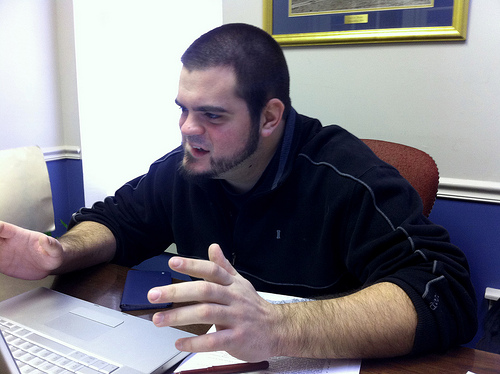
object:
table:
[59, 244, 498, 372]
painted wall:
[3, 2, 497, 349]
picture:
[257, 1, 474, 48]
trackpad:
[43, 310, 201, 340]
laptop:
[6, 259, 180, 367]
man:
[45, 10, 472, 352]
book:
[97, 246, 205, 324]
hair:
[165, 18, 321, 151]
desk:
[77, 255, 301, 331]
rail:
[43, 142, 498, 209]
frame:
[275, 24, 458, 39]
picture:
[263, 2, 467, 51]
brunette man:
[83, 19, 383, 285]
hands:
[8, 197, 278, 360]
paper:
[181, 287, 367, 372]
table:
[1, 225, 497, 369]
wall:
[437, 201, 499, 331]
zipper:
[244, 196, 323, 279]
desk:
[3, 261, 483, 371]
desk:
[14, 169, 499, 371]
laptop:
[0, 285, 212, 367]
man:
[43, 50, 471, 355]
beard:
[175, 121, 276, 191]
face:
[153, 14, 304, 189]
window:
[103, 43, 179, 131]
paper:
[171, 283, 361, 372]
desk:
[0, 249, 500, 372]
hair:
[274, 299, 416, 346]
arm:
[157, 173, 478, 362]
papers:
[292, 347, 359, 369]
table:
[415, 344, 480, 371]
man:
[136, 69, 486, 329]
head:
[175, 22, 290, 183]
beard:
[176, 115, 261, 182]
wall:
[220, 1, 499, 197]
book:
[119, 265, 172, 311]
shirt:
[72, 112, 477, 353]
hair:
[309, 297, 374, 339]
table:
[0, 261, 499, 371]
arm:
[146, 239, 476, 364]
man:
[17, 20, 471, 372]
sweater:
[69, 129, 469, 346]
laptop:
[4, 292, 206, 370]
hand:
[143, 242, 268, 363]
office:
[3, 3, 494, 370]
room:
[2, 0, 494, 368]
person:
[4, 21, 475, 362]